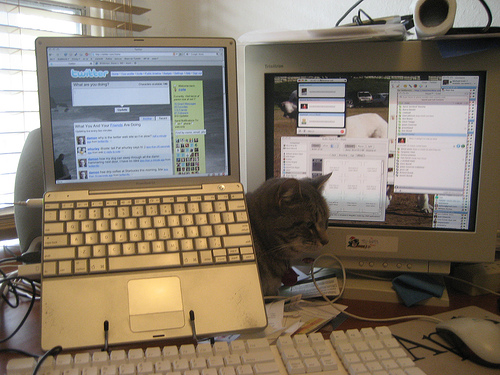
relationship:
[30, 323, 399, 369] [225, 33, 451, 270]
keyboard attached to computer